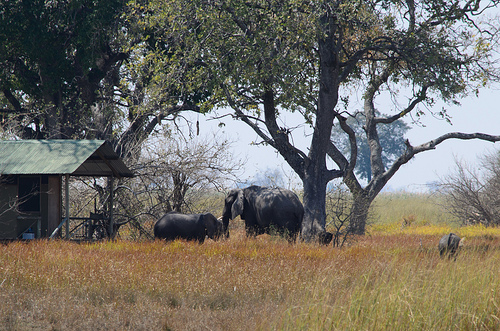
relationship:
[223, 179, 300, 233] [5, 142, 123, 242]
elephant by house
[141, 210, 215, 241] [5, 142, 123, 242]
elephant in front of house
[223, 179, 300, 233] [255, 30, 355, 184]
elephant near tree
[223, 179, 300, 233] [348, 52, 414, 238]
elephant near tree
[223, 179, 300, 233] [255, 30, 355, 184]
elephant under tree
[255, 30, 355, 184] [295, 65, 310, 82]
tree has leaves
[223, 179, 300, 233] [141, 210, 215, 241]
elephant caring for baby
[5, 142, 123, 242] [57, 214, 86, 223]
house has railing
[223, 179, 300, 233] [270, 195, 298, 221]
elephant has shadows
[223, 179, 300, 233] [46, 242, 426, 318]
elephant in field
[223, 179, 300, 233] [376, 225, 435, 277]
elephant in plain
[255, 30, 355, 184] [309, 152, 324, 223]
tree has trunk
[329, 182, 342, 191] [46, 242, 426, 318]
tree in field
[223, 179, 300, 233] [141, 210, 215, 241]
elephant facing elephant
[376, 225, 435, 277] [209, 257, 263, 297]
plain has grass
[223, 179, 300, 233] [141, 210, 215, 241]
elephant by elephant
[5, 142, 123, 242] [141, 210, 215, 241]
house near elephant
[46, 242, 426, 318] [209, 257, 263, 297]
field has grass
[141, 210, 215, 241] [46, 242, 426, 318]
elephant in field